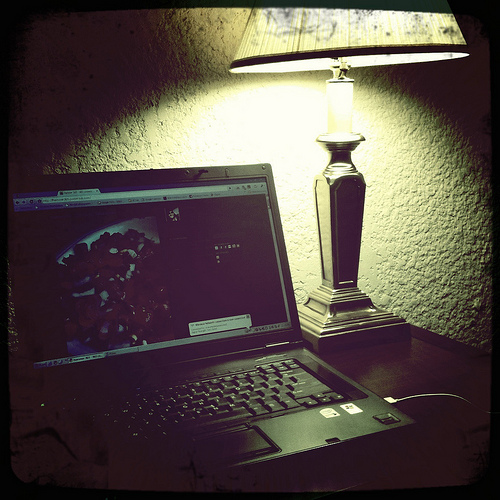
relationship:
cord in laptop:
[413, 385, 449, 407] [41, 180, 314, 444]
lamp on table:
[254, 17, 458, 152] [399, 325, 454, 370]